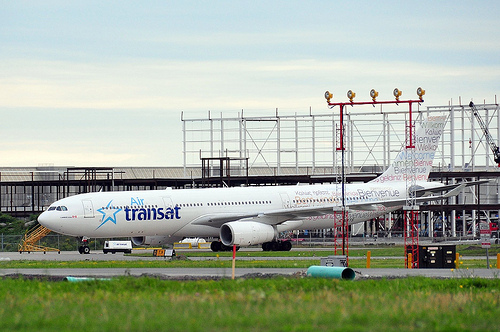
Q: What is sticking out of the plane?
A: A wing.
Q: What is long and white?
A: An airplane.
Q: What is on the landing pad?
A: A plane.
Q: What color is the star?
A: Blue.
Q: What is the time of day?
A: Daylight.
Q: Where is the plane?
A: Airport.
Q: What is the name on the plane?
A: Air transat.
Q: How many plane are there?
A: 1.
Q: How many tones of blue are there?
A: 2.